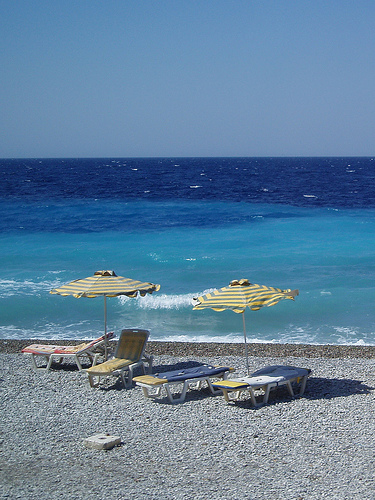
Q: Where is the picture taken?
A: Beach.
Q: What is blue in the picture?
A: The water.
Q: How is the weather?
A: Sunny.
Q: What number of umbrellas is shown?
A: Two.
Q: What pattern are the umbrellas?
A: Striped.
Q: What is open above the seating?
A: Umbrellas.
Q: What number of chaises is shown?
A: 4.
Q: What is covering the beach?
A: Pebbles.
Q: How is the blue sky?
A: Clear and cloudless.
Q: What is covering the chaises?
A: Cushions.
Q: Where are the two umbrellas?
A: On the beach.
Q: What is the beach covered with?
A: Pebbles.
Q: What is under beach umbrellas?
A: Recliners.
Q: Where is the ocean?
A: Behind the beach.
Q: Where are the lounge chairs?
A: On the shore.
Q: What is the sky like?
A: Cloudless.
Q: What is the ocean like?
A: Light and dark blue.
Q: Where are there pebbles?
A: On the shore.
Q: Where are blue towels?
A: On two lounge chairs on the right.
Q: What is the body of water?
A: Ocean.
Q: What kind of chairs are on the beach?
A: Chaise lounges.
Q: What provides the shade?
A: Umbrellas.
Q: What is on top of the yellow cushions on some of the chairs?
A: Towels.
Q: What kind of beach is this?
A: Pebbled.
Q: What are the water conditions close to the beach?
A: Calm.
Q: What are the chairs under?
A: Umbrellas.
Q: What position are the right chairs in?
A: Laying flat.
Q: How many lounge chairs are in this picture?
A: Four.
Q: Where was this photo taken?
A: The beach.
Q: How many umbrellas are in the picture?
A: Two.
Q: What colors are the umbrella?
A: Gray and yellow.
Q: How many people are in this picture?
A: Zero.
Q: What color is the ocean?
A: Blue.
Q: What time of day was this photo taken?
A: Day time.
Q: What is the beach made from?
A: Rocks.